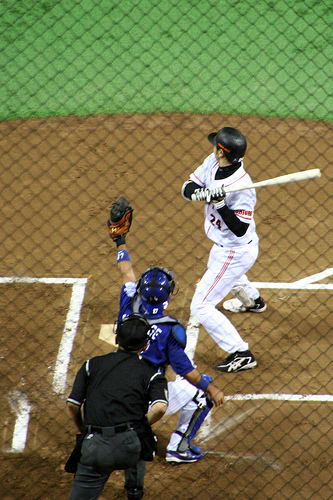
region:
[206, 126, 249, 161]
Black baseball helmet,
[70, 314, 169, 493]
Umpire black uniform and hat.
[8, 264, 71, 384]
White markings on the field.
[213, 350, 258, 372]
White and black atheltic shoes.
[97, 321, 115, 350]
Dusty home baseball plate.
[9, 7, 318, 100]
Green grassy baseball field.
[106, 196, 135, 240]
Brown and black baseball glove.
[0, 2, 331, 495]
Chainlink fence in back of baseball game.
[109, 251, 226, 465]
Batcatcher in blue and white uniform.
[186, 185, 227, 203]
Black and white baseball gloves.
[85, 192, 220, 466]
catcher reaching for the ball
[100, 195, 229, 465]
catcher in a blue jersey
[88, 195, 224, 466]
catcher with a blue helmet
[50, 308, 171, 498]
umpire in position to call pitch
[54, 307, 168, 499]
back of the umpire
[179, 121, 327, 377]
left handed batter not swinging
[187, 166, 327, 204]
baseball bat in hitting position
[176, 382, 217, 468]
catcher's gear for right leg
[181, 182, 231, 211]
batting gloves on the batter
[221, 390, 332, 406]
line not obliterated indicating early in game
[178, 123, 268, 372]
Baseball player in white at bat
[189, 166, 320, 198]
Blonde bat in hands of a baseball player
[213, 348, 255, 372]
Black and white shoe on a baseball player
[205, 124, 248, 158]
Black helmet on baseball batter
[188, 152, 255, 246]
White jersey with red piping on baseball player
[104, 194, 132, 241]
Black and orange mitt worn by a baseball catcher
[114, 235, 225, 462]
Catcher behind the plate in a baseball game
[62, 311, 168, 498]
Home plate umpire in dark clothing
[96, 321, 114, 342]
Part of home plate on a baseball field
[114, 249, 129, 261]
Blue and white armband on baseball catcher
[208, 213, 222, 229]
player's number on their jersey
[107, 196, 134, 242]
baseball mitt on catcher's hand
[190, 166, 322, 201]
bat in man's hand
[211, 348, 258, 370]
cleat on man's foot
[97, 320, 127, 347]
home base sitting on dirt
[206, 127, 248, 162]
helmet on batter's head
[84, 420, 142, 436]
belt around umpire's waist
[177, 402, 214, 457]
shinguard on catcher's shin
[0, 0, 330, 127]
green grass on ground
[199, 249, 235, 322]
red stripes on player's jersey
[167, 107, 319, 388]
baseball player at home plate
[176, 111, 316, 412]
baseball player holding a bat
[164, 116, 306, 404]
baseball player getting ready to swing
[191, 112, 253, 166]
baseball player wearing black helmet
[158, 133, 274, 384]
baseball player wearing white uniform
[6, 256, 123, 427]
white lines in the dirt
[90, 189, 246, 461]
catcher is crouched behind the baseball player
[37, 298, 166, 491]
the umpire is behind the catcher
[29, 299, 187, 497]
the umpire is wearing all black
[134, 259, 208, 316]
catcher is wearing a blue helmet